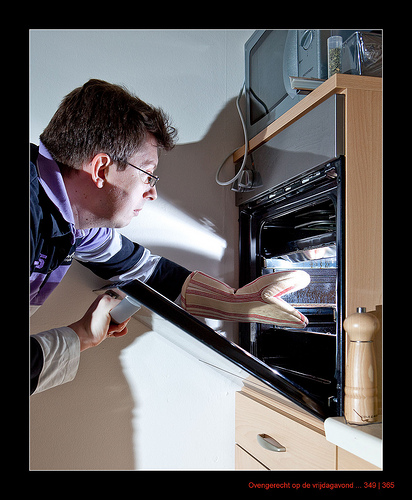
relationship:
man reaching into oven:
[29, 79, 313, 405] [86, 156, 346, 421]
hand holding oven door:
[78, 289, 130, 344] [90, 277, 318, 422]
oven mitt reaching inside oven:
[179, 264, 314, 332] [86, 156, 346, 421]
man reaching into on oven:
[29, 79, 313, 405] [91, 93, 344, 422]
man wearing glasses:
[29, 79, 313, 405] [111, 156, 158, 190]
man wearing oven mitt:
[29, 79, 313, 405] [179, 267, 310, 329]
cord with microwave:
[215, 79, 247, 186] [206, 105, 368, 343]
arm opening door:
[78, 227, 228, 332] [89, 277, 324, 423]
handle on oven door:
[91, 293, 144, 328] [89, 273, 336, 424]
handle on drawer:
[254, 430, 286, 455] [234, 391, 351, 467]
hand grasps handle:
[78, 289, 130, 344] [105, 294, 146, 328]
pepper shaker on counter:
[342, 306, 379, 423] [322, 412, 384, 469]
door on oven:
[89, 277, 324, 423] [91, 93, 344, 422]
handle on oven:
[91, 293, 144, 328] [104, 86, 354, 420]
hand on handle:
[78, 289, 130, 344] [89, 293, 145, 333]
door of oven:
[89, 277, 324, 423] [234, 173, 340, 408]